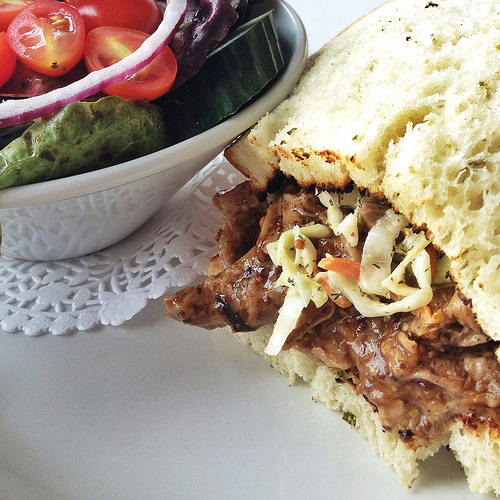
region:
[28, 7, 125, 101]
Tomatoes cut in half in bowl.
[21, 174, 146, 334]
Food inside white bowl.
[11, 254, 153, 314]
White bowl sitting on white doily.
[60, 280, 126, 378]
White doily sitting on white surface.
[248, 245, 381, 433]
Brown meat on sandwich.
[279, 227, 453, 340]
Coleslaw on sandwich.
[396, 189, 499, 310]
Sandwich on white bread.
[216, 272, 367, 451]
Sandwich sitting on white surface.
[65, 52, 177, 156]
Sliced red onion in bowl.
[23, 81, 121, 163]
Green lettuce in bowl.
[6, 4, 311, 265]
The bowl is white.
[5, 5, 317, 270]
The bowl is glass.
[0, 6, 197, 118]
The bowl has an onion ring in it.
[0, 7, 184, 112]
The bowl has cut tomatoes in it.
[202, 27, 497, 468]
This is a thick sandwich.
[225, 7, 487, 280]
The bread is toasted.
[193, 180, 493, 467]
A lot of meat is in the sandwich.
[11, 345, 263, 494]
The table is white.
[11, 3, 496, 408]
This is a sandwich and salad.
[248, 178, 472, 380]
This is cheese.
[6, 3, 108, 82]
cherry tomatoes cut in half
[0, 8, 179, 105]
sliced red onion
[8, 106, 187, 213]
green spinach in white bowl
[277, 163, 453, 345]
cole slaw on sandwich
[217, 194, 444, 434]
juicy steak in sauce on sandwich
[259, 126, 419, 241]
burnt edge of sandwich bread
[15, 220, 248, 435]
white Dolley on table top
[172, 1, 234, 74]
red cabbage in salad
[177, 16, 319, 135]
thick slice of cucumber in salad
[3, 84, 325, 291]
white glass salad bowl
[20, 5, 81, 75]
tomato in salad bowl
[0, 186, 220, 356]
doily under salad bowl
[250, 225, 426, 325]
coleslaw on toasted sandwich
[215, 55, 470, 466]
toasted barbequed meat sandwich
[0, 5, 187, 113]
purple onion in salad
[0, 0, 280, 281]
white round salad bowl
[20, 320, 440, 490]
white table top under sandwich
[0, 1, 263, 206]
greens in salad bowl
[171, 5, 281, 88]
purple cabbage in salad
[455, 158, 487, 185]
seeds in sandwich bread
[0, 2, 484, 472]
the table is white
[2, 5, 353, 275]
a bowl is on the table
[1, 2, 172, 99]
tomatoes and onions are in the bowl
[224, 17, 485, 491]
a sandwich is next to the bowl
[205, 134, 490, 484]
the sandwich is full of meat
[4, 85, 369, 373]
a white table cloth is under the bowl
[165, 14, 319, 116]
cucumbers are in the bowl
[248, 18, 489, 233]
the sandwich bread is white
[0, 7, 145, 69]
the tomatoes are red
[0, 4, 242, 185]
the onions are red and white